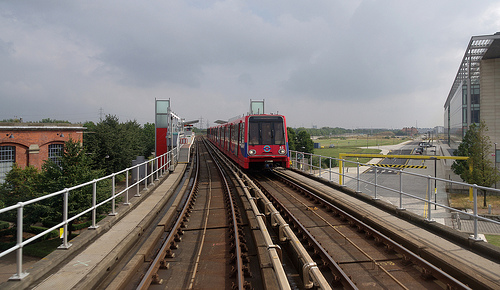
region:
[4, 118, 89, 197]
building is orange brick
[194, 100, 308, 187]
train is red with blue spots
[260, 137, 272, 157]
neon blue circle on train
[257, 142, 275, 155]
neon blue circle on train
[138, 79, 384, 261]
elevated train on tracks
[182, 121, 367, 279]
two sets of train tracks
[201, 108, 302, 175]
red commuter train on track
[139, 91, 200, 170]
platform on trackside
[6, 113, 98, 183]
red brick building in trees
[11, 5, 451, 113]
grey clouds in the sky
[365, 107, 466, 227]
highway in front of building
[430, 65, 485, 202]
glass fronted tall building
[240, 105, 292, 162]
large windshield on train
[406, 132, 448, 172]
cars on street below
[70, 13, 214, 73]
dark gray clouds in the sky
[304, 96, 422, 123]
white skies overhead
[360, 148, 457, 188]
yellow and black overhead post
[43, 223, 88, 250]
small yellow sign on post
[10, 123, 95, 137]
white roof on building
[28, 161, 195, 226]
large silver railing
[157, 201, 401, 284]
large brown train tracks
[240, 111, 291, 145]
large clear window front on bus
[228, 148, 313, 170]
lights on front of bus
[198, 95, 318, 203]
large red and blue passenger train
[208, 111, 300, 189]
red passenger train on tracks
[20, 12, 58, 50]
white clouds in blue sky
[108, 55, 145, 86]
white clouds in blue sky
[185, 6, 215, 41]
white clouds in blue sky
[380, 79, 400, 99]
white clouds in blue sky